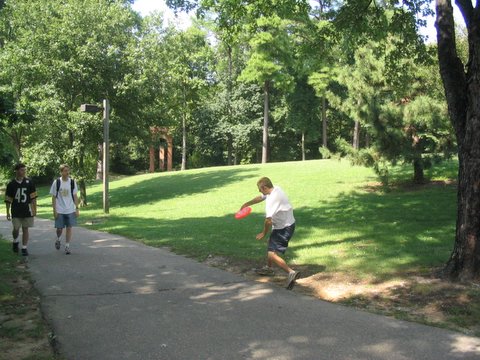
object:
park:
[14, 20, 474, 356]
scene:
[33, 68, 375, 327]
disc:
[232, 205, 251, 220]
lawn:
[146, 160, 425, 259]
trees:
[294, 35, 342, 163]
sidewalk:
[79, 245, 229, 352]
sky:
[141, 4, 231, 40]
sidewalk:
[18, 164, 255, 347]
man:
[47, 163, 80, 251]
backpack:
[54, 178, 77, 202]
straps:
[51, 171, 78, 203]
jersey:
[4, 178, 38, 218]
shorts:
[53, 210, 79, 229]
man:
[231, 172, 302, 291]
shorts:
[265, 223, 298, 256]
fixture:
[94, 93, 118, 222]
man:
[3, 162, 40, 257]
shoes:
[11, 239, 20, 255]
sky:
[137, 7, 478, 55]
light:
[37, 157, 445, 258]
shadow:
[37, 157, 445, 258]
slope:
[37, 144, 445, 259]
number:
[14, 188, 21, 203]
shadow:
[15, 191, 441, 322]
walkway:
[15, 191, 441, 322]